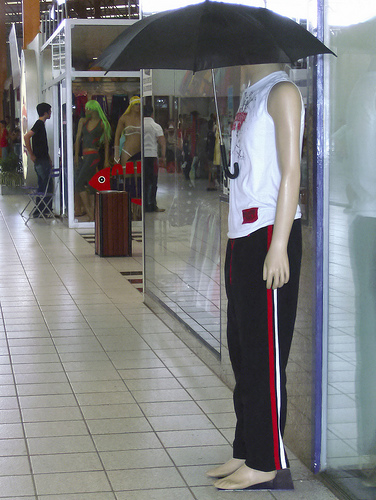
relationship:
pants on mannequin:
[224, 210, 302, 472] [208, 65, 308, 495]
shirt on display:
[227, 70, 304, 239] [245, 467, 294, 490]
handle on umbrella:
[222, 150, 240, 179] [86, 5, 336, 64]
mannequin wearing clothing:
[74, 98, 108, 219] [76, 116, 105, 195]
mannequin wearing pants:
[208, 65, 308, 495] [224, 215, 302, 470]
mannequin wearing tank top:
[218, 26, 316, 496] [217, 69, 306, 243]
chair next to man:
[20, 166, 61, 225] [22, 94, 62, 219]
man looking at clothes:
[21, 101, 79, 200] [20, 133, 62, 186]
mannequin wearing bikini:
[111, 92, 148, 197] [115, 123, 143, 158]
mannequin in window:
[208, 65, 308, 495] [123, 47, 370, 449]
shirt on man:
[25, 116, 51, 155] [25, 100, 55, 213]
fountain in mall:
[93, 185, 134, 261] [4, 18, 370, 498]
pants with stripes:
[203, 210, 301, 498] [264, 222, 286, 476]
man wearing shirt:
[23, 102, 52, 214] [24, 114, 54, 162]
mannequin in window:
[208, 65, 308, 495] [41, 36, 322, 392]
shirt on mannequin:
[220, 62, 364, 232] [201, 45, 319, 495]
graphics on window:
[77, 155, 120, 191] [66, 52, 170, 200]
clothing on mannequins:
[69, 117, 149, 200] [67, 95, 144, 220]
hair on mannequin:
[115, 90, 147, 115] [114, 90, 152, 190]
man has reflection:
[23, 102, 52, 214] [144, 106, 165, 211]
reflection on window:
[144, 106, 165, 211] [139, 58, 243, 358]